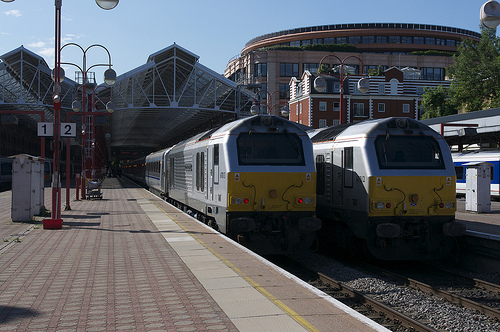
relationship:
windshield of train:
[228, 132, 299, 181] [102, 90, 329, 227]